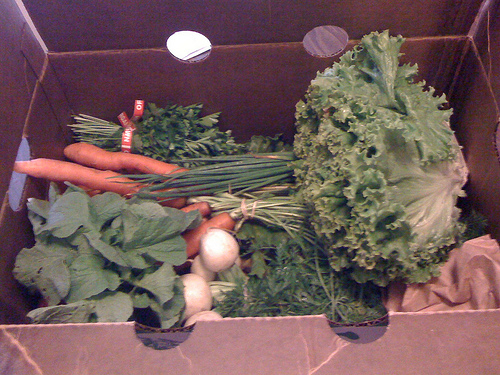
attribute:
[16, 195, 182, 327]
kales — these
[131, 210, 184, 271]
kale — fresh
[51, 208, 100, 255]
kale — fresh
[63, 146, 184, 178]
carrot — these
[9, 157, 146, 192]
carrot — these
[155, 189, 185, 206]
carrot — these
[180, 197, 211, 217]
carrot — these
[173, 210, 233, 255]
carrot — these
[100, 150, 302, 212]
green onions — two bunches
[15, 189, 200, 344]
leaves — green, color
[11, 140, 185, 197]
carrots — orange 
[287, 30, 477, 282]
lettuce — head of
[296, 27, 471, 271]
head — lettuce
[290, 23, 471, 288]
leaves — big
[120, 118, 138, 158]
lettering — white 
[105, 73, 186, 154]
label — red 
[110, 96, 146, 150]
band — red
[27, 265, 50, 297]
caterpillar holes — caterpillar 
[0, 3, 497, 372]
box — cardboard, brown, color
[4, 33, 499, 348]
box — brown, cardboard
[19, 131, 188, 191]
carrots — long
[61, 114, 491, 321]
vegetables — other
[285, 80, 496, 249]
lettuce — head of, romaine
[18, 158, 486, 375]
box — cardboard 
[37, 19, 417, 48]
surface — grey 